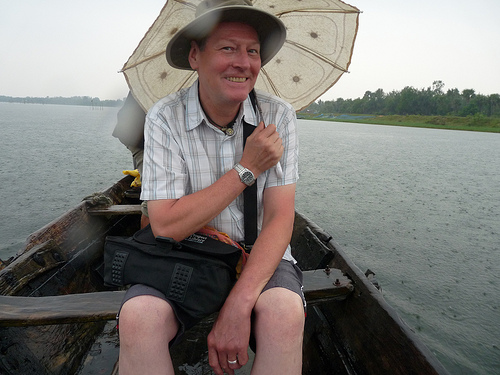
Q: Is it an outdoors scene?
A: Yes, it is outdoors.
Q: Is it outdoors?
A: Yes, it is outdoors.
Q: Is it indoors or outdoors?
A: It is outdoors.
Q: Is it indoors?
A: No, it is outdoors.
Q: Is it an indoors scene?
A: No, it is outdoors.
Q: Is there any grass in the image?
A: Yes, there is grass.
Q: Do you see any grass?
A: Yes, there is grass.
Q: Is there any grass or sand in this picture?
A: Yes, there is grass.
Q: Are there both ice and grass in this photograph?
A: No, there is grass but no ice.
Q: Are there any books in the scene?
A: No, there are no books.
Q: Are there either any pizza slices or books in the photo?
A: No, there are no books or pizza slices.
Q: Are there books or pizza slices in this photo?
A: No, there are no books or pizza slices.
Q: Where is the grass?
A: The grass is on the field.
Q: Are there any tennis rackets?
A: No, there are no tennis rackets.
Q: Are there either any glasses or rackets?
A: No, there are no rackets or glasses.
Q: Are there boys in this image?
A: No, there are no boys.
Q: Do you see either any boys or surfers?
A: No, there are no boys or surfers.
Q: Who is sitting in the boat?
A: The man is sitting in the boat.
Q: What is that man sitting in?
A: The man is sitting in the boat.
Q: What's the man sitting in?
A: The man is sitting in the boat.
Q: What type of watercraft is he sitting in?
A: The man is sitting in the boat.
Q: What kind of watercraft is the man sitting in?
A: The man is sitting in the boat.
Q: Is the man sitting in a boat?
A: Yes, the man is sitting in a boat.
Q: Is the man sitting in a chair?
A: No, the man is sitting in a boat.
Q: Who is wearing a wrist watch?
A: The man is wearing a wrist watch.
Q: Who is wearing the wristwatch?
A: The man is wearing a wrist watch.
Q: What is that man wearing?
A: The man is wearing a wristwatch.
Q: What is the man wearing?
A: The man is wearing a wristwatch.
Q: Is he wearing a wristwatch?
A: Yes, the man is wearing a wristwatch.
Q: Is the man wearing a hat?
A: No, the man is wearing a wristwatch.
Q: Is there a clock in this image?
A: No, there are no clocks.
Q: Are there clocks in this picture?
A: No, there are no clocks.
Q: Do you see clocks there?
A: No, there are no clocks.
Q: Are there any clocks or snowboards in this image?
A: No, there are no clocks or snowboards.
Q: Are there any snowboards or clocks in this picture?
A: No, there are no clocks or snowboards.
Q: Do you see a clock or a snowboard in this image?
A: No, there are no clocks or snowboards.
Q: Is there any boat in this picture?
A: Yes, there is a boat.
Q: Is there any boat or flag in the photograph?
A: Yes, there is a boat.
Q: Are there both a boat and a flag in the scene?
A: No, there is a boat but no flags.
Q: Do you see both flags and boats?
A: No, there is a boat but no flags.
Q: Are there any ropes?
A: No, there are no ropes.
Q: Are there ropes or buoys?
A: No, there are no ropes or buoys.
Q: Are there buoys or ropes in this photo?
A: No, there are no ropes or buoys.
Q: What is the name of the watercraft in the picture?
A: The watercraft is a boat.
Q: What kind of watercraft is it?
A: The watercraft is a boat.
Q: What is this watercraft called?
A: This is a boat.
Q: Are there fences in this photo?
A: No, there are no fences.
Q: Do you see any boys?
A: No, there are no boys.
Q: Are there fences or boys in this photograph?
A: No, there are no boys or fences.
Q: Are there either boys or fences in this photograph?
A: No, there are no boys or fences.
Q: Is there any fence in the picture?
A: No, there are no fences.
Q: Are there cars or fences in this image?
A: No, there are no fences or cars.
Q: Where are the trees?
A: The trees are on the field.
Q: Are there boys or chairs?
A: No, there are no boys or chairs.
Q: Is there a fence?
A: No, there are no fences.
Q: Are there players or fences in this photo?
A: No, there are no fences or players.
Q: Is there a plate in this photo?
A: No, there are no plates.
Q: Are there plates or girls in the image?
A: No, there are no plates or girls.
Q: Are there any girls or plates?
A: No, there are no plates or girls.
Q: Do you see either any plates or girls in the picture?
A: No, there are no plates or girls.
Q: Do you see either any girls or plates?
A: No, there are no plates or girls.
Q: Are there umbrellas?
A: Yes, there is an umbrella.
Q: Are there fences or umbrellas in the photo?
A: Yes, there is an umbrella.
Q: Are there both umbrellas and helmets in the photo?
A: No, there is an umbrella but no helmets.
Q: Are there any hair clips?
A: No, there are no hair clips.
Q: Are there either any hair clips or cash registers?
A: No, there are no hair clips or cash registers.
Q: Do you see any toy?
A: No, there are no toys.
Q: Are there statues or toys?
A: No, there are no toys or statues.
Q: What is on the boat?
A: The water is on the boat.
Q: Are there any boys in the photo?
A: No, there are no boys.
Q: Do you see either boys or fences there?
A: No, there are no boys or fences.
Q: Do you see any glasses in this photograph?
A: No, there are no glasses.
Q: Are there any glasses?
A: No, there are no glasses.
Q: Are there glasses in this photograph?
A: No, there are no glasses.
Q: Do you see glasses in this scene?
A: No, there are no glasses.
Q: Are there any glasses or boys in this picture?
A: No, there are no glasses or boys.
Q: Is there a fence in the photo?
A: No, there are no fences.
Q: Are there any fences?
A: No, there are no fences.